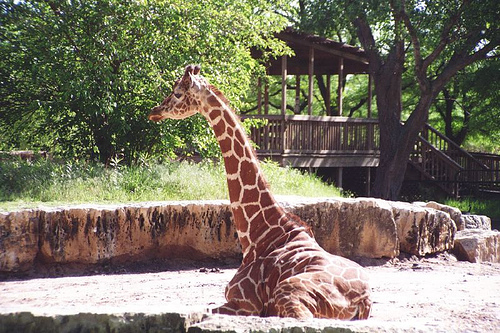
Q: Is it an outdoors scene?
A: Yes, it is outdoors.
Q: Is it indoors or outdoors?
A: It is outdoors.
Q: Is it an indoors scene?
A: No, it is outdoors.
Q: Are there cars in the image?
A: No, there are no cars.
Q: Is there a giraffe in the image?
A: Yes, there is a giraffe.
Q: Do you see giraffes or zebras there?
A: Yes, there is a giraffe.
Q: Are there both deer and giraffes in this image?
A: No, there is a giraffe but no deer.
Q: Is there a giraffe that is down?
A: Yes, there is a giraffe that is down.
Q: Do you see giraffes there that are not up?
A: Yes, there is a giraffe that is down .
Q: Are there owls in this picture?
A: No, there are no owls.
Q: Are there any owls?
A: No, there are no owls.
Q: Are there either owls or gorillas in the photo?
A: No, there are no owls or gorillas.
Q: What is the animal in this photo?
A: The animal is a giraffe.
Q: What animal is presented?
A: The animal is a giraffe.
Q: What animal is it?
A: The animal is a giraffe.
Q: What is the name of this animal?
A: This is a giraffe.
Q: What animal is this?
A: This is a giraffe.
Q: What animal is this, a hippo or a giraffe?
A: This is a giraffe.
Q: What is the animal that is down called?
A: The animal is a giraffe.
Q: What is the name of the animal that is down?
A: The animal is a giraffe.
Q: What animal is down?
A: The animal is a giraffe.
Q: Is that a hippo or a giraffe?
A: That is a giraffe.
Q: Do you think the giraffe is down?
A: Yes, the giraffe is down.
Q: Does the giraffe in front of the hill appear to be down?
A: Yes, the giraffe is down.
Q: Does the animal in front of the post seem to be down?
A: Yes, the giraffe is down.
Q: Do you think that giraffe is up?
A: No, the giraffe is down.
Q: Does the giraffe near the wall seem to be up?
A: No, the giraffe is down.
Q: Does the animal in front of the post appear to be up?
A: No, the giraffe is down.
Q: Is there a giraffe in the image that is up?
A: No, there is a giraffe but it is down.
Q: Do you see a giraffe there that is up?
A: No, there is a giraffe but it is down.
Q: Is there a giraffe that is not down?
A: No, there is a giraffe but it is down.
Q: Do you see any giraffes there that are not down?
A: No, there is a giraffe but it is down.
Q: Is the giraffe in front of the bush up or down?
A: The giraffe is down.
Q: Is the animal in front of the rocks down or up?
A: The giraffe is down.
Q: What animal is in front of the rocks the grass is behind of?
A: The giraffe is in front of the rocks.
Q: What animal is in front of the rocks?
A: The giraffe is in front of the rocks.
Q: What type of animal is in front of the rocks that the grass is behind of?
A: The animal is a giraffe.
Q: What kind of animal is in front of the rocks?
A: The animal is a giraffe.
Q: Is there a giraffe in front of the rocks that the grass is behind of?
A: Yes, there is a giraffe in front of the rocks.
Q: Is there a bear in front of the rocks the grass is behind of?
A: No, there is a giraffe in front of the rocks.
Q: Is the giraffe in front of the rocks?
A: Yes, the giraffe is in front of the rocks.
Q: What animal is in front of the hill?
A: The giraffe is in front of the hill.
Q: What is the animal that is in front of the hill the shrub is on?
A: The animal is a giraffe.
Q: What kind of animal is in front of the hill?
A: The animal is a giraffe.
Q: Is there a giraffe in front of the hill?
A: Yes, there is a giraffe in front of the hill.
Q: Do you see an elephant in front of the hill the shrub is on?
A: No, there is a giraffe in front of the hill.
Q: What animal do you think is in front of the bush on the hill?
A: The giraffe is in front of the bush.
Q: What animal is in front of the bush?
A: The giraffe is in front of the bush.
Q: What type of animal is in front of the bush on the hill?
A: The animal is a giraffe.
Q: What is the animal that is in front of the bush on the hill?
A: The animal is a giraffe.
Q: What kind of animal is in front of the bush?
A: The animal is a giraffe.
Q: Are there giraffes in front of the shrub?
A: Yes, there is a giraffe in front of the shrub.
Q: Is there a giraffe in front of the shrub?
A: Yes, there is a giraffe in front of the shrub.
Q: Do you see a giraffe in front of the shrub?
A: Yes, there is a giraffe in front of the shrub.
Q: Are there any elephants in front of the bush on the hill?
A: No, there is a giraffe in front of the bush.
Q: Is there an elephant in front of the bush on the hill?
A: No, there is a giraffe in front of the bush.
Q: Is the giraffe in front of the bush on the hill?
A: Yes, the giraffe is in front of the shrub.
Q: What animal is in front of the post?
A: The giraffe is in front of the post.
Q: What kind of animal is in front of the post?
A: The animal is a giraffe.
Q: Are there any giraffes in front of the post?
A: Yes, there is a giraffe in front of the post.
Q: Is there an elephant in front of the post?
A: No, there is a giraffe in front of the post.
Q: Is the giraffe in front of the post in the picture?
A: Yes, the giraffe is in front of the post.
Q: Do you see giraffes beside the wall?
A: Yes, there is a giraffe beside the wall.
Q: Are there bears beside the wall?
A: No, there is a giraffe beside the wall.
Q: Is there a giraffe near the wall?
A: Yes, there is a giraffe near the wall.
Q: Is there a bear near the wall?
A: No, there is a giraffe near the wall.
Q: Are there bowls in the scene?
A: No, there are no bowls.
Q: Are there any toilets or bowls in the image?
A: No, there are no bowls or toilets.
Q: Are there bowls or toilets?
A: No, there are no bowls or toilets.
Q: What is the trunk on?
A: The trunk is on the tree.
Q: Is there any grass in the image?
A: Yes, there is grass.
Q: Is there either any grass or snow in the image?
A: Yes, there is grass.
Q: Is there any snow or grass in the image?
A: Yes, there is grass.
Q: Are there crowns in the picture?
A: No, there are no crowns.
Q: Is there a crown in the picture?
A: No, there are no crowns.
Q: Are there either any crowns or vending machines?
A: No, there are no crowns or vending machines.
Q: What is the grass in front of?
A: The grass is in front of the trees.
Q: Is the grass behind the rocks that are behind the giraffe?
A: Yes, the grass is behind the rocks.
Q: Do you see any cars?
A: No, there are no cars.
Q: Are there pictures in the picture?
A: No, there are no pictures.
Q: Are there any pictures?
A: No, there are no pictures.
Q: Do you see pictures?
A: No, there are no pictures.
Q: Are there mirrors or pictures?
A: No, there are no pictures or mirrors.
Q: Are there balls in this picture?
A: No, there are no balls.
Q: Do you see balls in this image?
A: No, there are no balls.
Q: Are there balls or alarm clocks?
A: No, there are no balls or alarm clocks.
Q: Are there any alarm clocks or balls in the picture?
A: No, there are no balls or alarm clocks.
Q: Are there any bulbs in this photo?
A: No, there are no bulbs.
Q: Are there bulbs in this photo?
A: No, there are no bulbs.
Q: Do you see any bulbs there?
A: No, there are no bulbs.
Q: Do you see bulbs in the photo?
A: No, there are no bulbs.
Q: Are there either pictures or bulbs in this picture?
A: No, there are no bulbs or pictures.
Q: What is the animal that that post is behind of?
A: The animal is a giraffe.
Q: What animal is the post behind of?
A: The post is behind the giraffe.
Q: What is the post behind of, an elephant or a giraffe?
A: The post is behind a giraffe.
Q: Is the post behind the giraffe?
A: Yes, the post is behind the giraffe.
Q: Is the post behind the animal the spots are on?
A: Yes, the post is behind the giraffe.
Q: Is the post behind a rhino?
A: No, the post is behind the giraffe.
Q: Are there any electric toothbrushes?
A: No, there are no electric toothbrushes.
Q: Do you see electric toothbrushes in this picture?
A: No, there are no electric toothbrushes.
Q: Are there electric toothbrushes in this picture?
A: No, there are no electric toothbrushes.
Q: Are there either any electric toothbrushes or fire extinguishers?
A: No, there are no electric toothbrushes or fire extinguishers.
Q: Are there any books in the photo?
A: No, there are no books.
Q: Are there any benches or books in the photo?
A: No, there are no books or benches.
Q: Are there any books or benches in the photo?
A: No, there are no books or benches.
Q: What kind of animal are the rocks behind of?
A: The rocks are behind the giraffe.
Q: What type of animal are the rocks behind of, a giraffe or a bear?
A: The rocks are behind a giraffe.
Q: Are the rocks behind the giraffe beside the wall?
A: Yes, the rocks are behind the giraffe.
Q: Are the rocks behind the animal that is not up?
A: Yes, the rocks are behind the giraffe.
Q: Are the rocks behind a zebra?
A: No, the rocks are behind the giraffe.